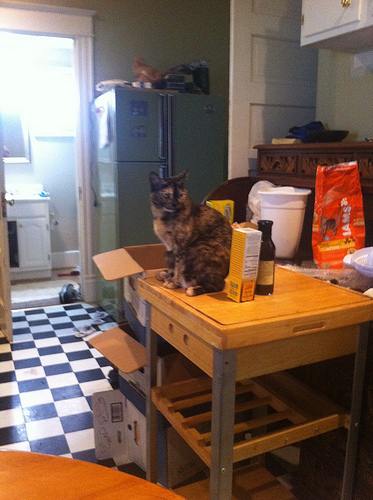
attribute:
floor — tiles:
[9, 341, 72, 434]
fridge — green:
[89, 88, 222, 317]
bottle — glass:
[255, 218, 275, 298]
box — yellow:
[218, 222, 259, 297]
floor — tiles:
[31, 333, 75, 433]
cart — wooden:
[127, 264, 371, 499]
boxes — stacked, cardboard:
[85, 235, 253, 483]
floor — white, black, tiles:
[3, 294, 371, 498]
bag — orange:
[306, 160, 369, 275]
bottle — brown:
[247, 219, 281, 299]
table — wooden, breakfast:
[131, 258, 371, 498]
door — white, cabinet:
[300, 9, 361, 42]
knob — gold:
[300, 14, 306, 25]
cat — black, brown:
[146, 168, 233, 294]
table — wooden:
[0, 449, 194, 498]